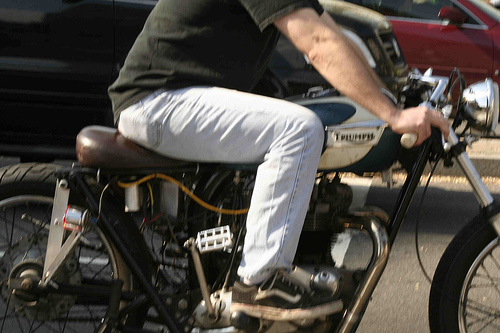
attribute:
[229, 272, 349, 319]
shoes — black, white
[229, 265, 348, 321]
shoes — white, black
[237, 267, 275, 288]
socks — white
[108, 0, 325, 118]
shirt — black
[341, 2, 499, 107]
car — red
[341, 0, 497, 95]
car — red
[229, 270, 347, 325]
shoe — black, white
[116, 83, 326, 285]
jeans — blue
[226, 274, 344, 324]
shoe — black, white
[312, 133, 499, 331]
road — tarmac, gray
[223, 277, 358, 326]
shoes — dirty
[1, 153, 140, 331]
tire — back, rear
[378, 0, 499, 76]
vehicle — red, smaller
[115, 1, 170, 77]
door — black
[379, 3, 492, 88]
car — red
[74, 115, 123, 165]
seat — brown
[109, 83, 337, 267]
pants — white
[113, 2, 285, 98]
shirt — black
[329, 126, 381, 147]
print — black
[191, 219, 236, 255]
pedal — white, silver